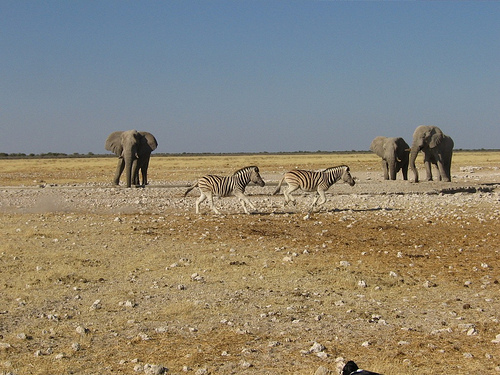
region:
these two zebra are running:
[177, 140, 381, 220]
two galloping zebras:
[172, 148, 397, 254]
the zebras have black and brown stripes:
[179, 139, 394, 251]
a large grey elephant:
[83, 100, 190, 222]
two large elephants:
[357, 79, 476, 210]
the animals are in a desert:
[1, 90, 497, 312]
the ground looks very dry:
[4, 157, 497, 371]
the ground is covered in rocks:
[9, 176, 498, 373]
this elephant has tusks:
[100, 119, 187, 194]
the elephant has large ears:
[98, 112, 176, 207]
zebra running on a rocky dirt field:
[180, 162, 269, 217]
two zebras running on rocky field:
[176, 163, 358, 215]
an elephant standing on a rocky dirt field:
[103, 127, 162, 188]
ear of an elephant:
[102, 128, 124, 157]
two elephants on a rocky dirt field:
[366, 123, 456, 183]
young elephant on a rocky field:
[370, 135, 408, 180]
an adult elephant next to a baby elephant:
[370, 123, 458, 184]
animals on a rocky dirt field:
[102, 123, 459, 217]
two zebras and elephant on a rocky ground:
[101, 126, 356, 219]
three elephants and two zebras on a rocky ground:
[101, 121, 458, 218]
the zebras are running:
[174, 150, 359, 228]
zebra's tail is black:
[179, 187, 197, 204]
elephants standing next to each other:
[367, 121, 455, 190]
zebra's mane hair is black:
[229, 163, 260, 179]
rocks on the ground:
[5, 176, 495, 367]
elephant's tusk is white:
[389, 153, 406, 170]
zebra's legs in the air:
[276, 182, 300, 214]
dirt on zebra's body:
[277, 163, 329, 201]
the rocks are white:
[2, 172, 497, 371]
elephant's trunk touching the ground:
[407, 152, 424, 185]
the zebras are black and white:
[150, 135, 360, 230]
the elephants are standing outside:
[47, 83, 470, 215]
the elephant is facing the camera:
[80, 116, 170, 189]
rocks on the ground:
[140, 217, 464, 357]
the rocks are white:
[357, 183, 470, 253]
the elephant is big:
[89, 117, 174, 204]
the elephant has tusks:
[105, 146, 147, 173]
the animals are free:
[57, 84, 473, 244]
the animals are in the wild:
[35, 67, 475, 266]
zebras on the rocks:
[190, 156, 364, 220]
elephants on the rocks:
[368, 126, 465, 191]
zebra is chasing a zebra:
[178, 135, 369, 235]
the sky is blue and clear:
[12, 8, 483, 106]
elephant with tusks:
[391, 118, 443, 157]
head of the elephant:
[407, 117, 452, 154]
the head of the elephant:
[365, 130, 404, 166]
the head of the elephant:
[98, 122, 165, 162]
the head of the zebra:
[240, 157, 273, 194]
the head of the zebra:
[324, 163, 358, 189]